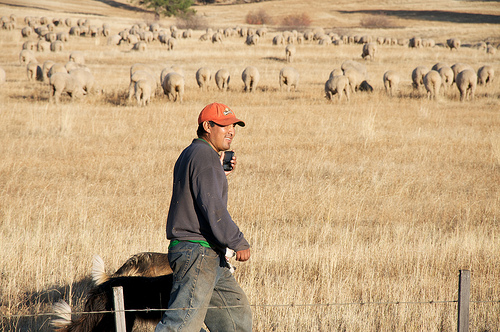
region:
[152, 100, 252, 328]
a man in an orange hat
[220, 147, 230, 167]
a black mobile phone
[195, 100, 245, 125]
an orange baseball cap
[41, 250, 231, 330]
two dogs walking beside the man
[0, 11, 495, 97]
a herd of animals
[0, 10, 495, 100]
a herd of animals in a pasture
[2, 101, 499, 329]
a rancher walking beside a barb wire fence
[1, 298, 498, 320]
metal wire nailed to a wooden pole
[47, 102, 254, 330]
a rancher walking beside two dogs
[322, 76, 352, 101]
sheep in the field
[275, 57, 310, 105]
sheep in the field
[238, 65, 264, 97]
sheep in the field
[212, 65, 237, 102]
sheep in the field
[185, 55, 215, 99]
sheep in the field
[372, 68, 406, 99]
sheep in the field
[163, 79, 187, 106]
sheep in the field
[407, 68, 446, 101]
sheep in the field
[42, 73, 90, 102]
sheep in the field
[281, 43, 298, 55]
sheep in the field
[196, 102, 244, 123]
Orange hat on farmers head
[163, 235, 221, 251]
green undershirt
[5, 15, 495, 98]
This is a herd of many sheep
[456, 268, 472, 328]
straight fence post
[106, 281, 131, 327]
slanted fence post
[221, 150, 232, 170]
farmers cell phone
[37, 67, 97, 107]
sheep eating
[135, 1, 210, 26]
tree in the distance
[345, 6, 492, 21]
shadow from a large tree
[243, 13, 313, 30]
bush type tree in the distances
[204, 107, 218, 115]
man wearing red cap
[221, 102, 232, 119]
symbol on red cap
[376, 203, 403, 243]
tall brown hay in field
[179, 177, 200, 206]
man wearing blue sweater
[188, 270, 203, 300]
man wearing grey jeans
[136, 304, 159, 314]
silver bob wire on wood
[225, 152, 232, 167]
black cell phone face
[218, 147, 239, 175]
cellphone in mans hand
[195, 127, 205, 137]
man has black hair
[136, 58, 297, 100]
large elephants in field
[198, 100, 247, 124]
Red cap on man's head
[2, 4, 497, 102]
Herd of sheep in a field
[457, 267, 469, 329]
Wooden fence post in field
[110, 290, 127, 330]
Wooden fence post in field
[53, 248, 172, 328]
Two sheepdogs with man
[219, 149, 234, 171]
Cell phone in man's hand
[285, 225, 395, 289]
Tan grass stalks in field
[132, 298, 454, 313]
Barbed wire between fence posts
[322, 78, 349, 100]
Sheep grazing in a field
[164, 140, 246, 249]
Black sweatshirt on man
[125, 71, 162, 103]
a white sheep in a field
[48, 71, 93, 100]
a white sheep in a field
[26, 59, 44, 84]
a white sheep in a field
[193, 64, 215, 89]
a white sheep in a field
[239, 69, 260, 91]
a white sheep in a field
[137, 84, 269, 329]
man walking in field